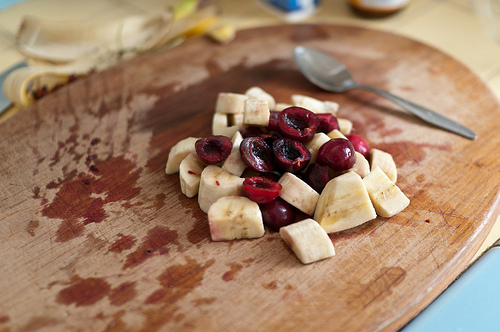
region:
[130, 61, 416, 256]
Cut up bananas and cherries.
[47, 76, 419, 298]
Cherries and bananas on a cutting board.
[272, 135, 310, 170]
A cherry that is cut in half.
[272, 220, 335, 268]
A cut up piece of banana.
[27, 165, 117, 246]
Moisture on a cutting board.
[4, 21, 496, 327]
A cutting board made out of wood.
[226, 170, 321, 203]
A piece of cherry next to a piece of banana.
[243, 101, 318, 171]
Cherries that have been diced in half.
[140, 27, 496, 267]
A spoon next to diced cherries and bananas.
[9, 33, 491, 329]
A spoon sitting on a wooden cutting board.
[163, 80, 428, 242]
Chunks of banana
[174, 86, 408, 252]
Chunks of cherries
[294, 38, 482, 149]
Silver spoon sitting near the fruit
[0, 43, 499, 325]
Wooden cutting board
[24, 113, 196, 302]
Juice stains on the wooden board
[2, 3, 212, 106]
Blurry banana peel in the background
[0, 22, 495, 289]
Scratches and scuffs on the cutting board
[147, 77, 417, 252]
A small pile of fruit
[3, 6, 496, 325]
Countertop the cutting board is on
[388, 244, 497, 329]
Blue countertop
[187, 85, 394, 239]
bananas and cherries are chopped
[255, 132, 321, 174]
cherry is cut in half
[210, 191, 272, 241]
banana has been chopped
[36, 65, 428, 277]
cutting board is made of wood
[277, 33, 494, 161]
a spoon is next to the fruit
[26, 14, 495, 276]
fruit is on the cutting board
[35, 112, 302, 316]
cutting board is brown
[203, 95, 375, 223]
cherries are with bananas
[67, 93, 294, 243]
the cutting board is wet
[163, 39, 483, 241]
spoon on a cutting board beside fruit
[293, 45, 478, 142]
shiny metal spoon on cutting board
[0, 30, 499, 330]
oval wood cutting board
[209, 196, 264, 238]
banana slices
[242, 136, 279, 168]
cherry slices on banana slices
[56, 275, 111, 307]
wet spots on cutting board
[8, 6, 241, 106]
banana peel behind cutting board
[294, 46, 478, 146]
spoon next to banana slice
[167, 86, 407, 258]
a pile of fruit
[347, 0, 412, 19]
jar behind cutting board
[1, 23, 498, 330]
cutting board is brown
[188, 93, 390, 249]
cherries and bananas cut up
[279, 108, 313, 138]
a slice of cherry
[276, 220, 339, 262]
a banana slice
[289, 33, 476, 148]
a grey metal spoon on a cutting board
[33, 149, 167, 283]
cherry juice on a cutting board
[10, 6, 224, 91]
a banana peel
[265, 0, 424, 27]
the edge of two containers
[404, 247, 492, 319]
the wooden edge of a cutting board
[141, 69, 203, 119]
a wet area of a cutting board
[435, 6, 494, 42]
a wooden table